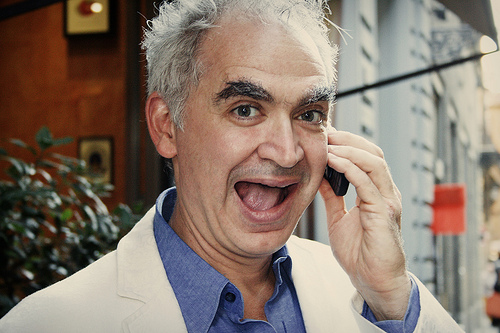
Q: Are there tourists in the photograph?
A: No, there are no tourists.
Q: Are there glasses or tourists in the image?
A: No, there are no tourists or glasses.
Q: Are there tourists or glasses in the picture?
A: No, there are no tourists or glasses.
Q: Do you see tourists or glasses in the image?
A: No, there are no tourists or glasses.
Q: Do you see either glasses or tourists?
A: No, there are no tourists or glasses.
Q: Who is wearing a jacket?
A: The gentleman is wearing a jacket.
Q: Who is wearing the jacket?
A: The gentleman is wearing a jacket.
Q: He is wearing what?
A: The gentleman is wearing a jacket.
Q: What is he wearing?
A: The gentleman is wearing a jacket.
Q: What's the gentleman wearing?
A: The gentleman is wearing a jacket.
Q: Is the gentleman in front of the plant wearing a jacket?
A: Yes, the gentleman is wearing a jacket.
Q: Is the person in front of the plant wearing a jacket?
A: Yes, the gentleman is wearing a jacket.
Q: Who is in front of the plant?
A: The gentleman is in front of the plant.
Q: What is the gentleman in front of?
A: The gentleman is in front of the plant.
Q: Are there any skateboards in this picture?
A: No, there are no skateboards.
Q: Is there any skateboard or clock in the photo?
A: No, there are no skateboards or clocks.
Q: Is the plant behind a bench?
A: No, the plant is behind a gentleman.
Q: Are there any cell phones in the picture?
A: Yes, there is a cell phone.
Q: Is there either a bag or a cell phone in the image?
A: Yes, there is a cell phone.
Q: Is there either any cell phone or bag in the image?
A: Yes, there is a cell phone.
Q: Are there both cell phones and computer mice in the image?
A: No, there is a cell phone but no computer mice.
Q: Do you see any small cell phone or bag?
A: Yes, there is a small cell phone.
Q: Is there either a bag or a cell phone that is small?
A: Yes, the cell phone is small.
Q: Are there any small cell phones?
A: Yes, there is a small cell phone.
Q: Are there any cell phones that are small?
A: Yes, there is a cell phone that is small.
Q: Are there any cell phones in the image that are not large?
A: Yes, there is a small cell phone.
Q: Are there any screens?
A: No, there are no screens.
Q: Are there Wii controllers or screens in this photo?
A: No, there are no screens or Wii controllers.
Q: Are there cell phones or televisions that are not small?
A: No, there is a cell phone but it is small.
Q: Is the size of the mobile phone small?
A: Yes, the mobile phone is small.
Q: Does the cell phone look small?
A: Yes, the cell phone is small.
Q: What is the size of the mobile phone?
A: The mobile phone is small.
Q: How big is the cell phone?
A: The cell phone is small.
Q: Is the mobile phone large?
A: No, the mobile phone is small.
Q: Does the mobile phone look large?
A: No, the mobile phone is small.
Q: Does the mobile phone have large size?
A: No, the mobile phone is small.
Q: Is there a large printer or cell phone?
A: No, there is a cell phone but it is small.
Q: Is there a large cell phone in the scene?
A: No, there is a cell phone but it is small.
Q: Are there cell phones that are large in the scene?
A: No, there is a cell phone but it is small.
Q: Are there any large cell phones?
A: No, there is a cell phone but it is small.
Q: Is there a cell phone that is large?
A: No, there is a cell phone but it is small.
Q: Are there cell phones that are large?
A: No, there is a cell phone but it is small.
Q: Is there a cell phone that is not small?
A: No, there is a cell phone but it is small.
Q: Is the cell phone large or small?
A: The cell phone is small.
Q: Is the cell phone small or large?
A: The cell phone is small.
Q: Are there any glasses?
A: No, there are no glasses.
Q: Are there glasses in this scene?
A: No, there are no glasses.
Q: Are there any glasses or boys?
A: No, there are no glasses or boys.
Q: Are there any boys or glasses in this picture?
A: No, there are no glasses or boys.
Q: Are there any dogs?
A: No, there are no dogs.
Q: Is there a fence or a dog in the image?
A: No, there are no dogs or fences.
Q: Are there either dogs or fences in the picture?
A: No, there are no dogs or fences.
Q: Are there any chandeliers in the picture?
A: No, there are no chandeliers.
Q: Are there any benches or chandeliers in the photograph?
A: No, there are no chandeliers or benches.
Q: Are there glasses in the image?
A: No, there are no glasses.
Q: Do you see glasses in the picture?
A: No, there are no glasses.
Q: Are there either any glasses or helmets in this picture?
A: No, there are no glasses or helmets.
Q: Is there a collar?
A: Yes, there is a collar.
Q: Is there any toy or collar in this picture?
A: Yes, there is a collar.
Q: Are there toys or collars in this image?
A: Yes, there is a collar.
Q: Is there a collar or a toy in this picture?
A: Yes, there is a collar.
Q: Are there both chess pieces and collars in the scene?
A: No, there is a collar but no chess pieces.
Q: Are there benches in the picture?
A: No, there are no benches.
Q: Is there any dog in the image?
A: No, there are no dogs.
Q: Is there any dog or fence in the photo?
A: No, there are no dogs or fences.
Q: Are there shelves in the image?
A: No, there are no shelves.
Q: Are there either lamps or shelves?
A: No, there are no shelves or lamps.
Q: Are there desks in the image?
A: No, there are no desks.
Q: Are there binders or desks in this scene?
A: No, there are no desks or binders.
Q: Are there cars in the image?
A: No, there are no cars.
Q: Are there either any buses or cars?
A: No, there are no cars or buses.